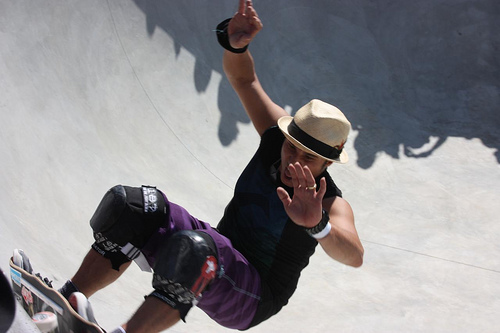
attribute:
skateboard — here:
[8, 256, 108, 332]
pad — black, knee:
[153, 230, 206, 296]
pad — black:
[91, 185, 171, 245]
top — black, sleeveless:
[216, 126, 341, 305]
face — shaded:
[280, 139, 324, 188]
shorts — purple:
[137, 201, 263, 329]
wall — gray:
[0, 1, 498, 332]